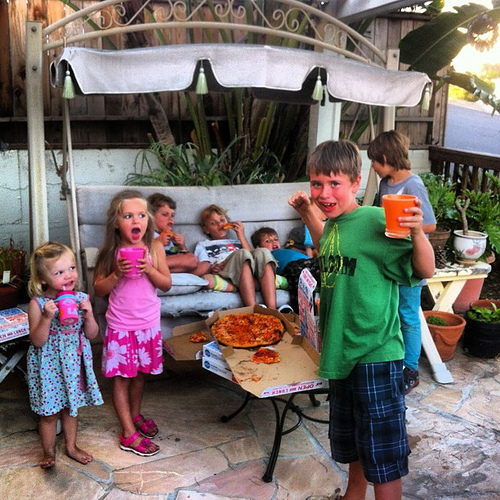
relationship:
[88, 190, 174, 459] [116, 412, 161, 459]
child has sandles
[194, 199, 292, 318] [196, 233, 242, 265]
boy has shirt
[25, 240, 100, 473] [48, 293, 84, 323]
child carrying cup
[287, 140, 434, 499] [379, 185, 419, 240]
boy carrying cup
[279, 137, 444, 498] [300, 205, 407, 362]
boy wearing shirt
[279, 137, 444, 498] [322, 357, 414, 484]
boy wearing shorts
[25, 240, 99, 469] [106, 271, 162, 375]
child wearing pink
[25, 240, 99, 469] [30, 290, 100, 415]
child wearing dress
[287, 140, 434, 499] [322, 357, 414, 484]
boy wearing shorts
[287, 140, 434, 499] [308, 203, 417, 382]
boy wearing tee shirt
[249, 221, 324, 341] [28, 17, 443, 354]
boy sitting on a swing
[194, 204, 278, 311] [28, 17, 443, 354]
boy sitting on a swing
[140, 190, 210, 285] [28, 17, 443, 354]
boy sitting on a swing